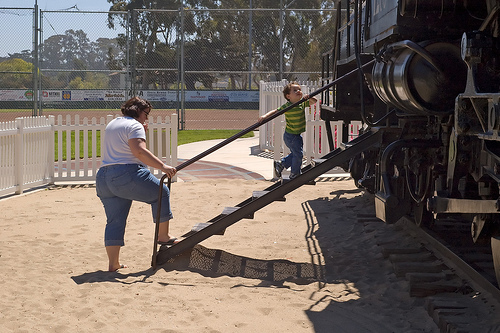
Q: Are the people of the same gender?
A: No, they are both male and female.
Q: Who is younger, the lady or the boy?
A: The boy is younger than the lady.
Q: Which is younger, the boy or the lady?
A: The boy is younger than the lady.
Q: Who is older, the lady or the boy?
A: The lady is older than the boy.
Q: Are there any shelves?
A: No, there are no shelves.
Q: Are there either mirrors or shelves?
A: No, there are no shelves or mirrors.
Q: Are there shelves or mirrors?
A: No, there are no shelves or mirrors.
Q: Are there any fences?
A: Yes, there is a fence.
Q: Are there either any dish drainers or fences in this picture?
A: Yes, there is a fence.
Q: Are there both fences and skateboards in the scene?
A: No, there is a fence but no skateboards.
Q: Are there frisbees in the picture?
A: No, there are no frisbees.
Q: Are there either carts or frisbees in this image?
A: No, there are no frisbees or carts.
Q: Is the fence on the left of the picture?
A: Yes, the fence is on the left of the image.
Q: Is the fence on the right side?
A: No, the fence is on the left of the image.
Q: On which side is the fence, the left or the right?
A: The fence is on the left of the image.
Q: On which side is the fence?
A: The fence is on the left of the image.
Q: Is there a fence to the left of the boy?
A: Yes, there is a fence to the left of the boy.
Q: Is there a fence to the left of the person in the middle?
A: Yes, there is a fence to the left of the boy.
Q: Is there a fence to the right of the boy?
A: No, the fence is to the left of the boy.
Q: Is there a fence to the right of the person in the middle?
A: No, the fence is to the left of the boy.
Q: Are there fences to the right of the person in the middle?
A: No, the fence is to the left of the boy.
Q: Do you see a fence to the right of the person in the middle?
A: No, the fence is to the left of the boy.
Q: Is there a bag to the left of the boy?
A: No, there is a fence to the left of the boy.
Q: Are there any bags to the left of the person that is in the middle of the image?
A: No, there is a fence to the left of the boy.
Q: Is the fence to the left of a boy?
A: Yes, the fence is to the left of a boy.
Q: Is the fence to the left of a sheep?
A: No, the fence is to the left of a boy.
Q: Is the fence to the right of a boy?
A: No, the fence is to the left of a boy.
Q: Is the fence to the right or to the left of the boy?
A: The fence is to the left of the boy.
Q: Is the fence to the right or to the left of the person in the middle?
A: The fence is to the left of the boy.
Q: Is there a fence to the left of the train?
A: Yes, there is a fence to the left of the train.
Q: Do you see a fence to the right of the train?
A: No, the fence is to the left of the train.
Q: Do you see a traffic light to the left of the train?
A: No, there is a fence to the left of the train.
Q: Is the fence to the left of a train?
A: Yes, the fence is to the left of a train.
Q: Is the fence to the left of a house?
A: No, the fence is to the left of a train.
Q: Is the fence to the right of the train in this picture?
A: No, the fence is to the left of the train.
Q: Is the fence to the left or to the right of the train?
A: The fence is to the left of the train.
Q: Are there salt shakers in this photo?
A: No, there are no salt shakers.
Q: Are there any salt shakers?
A: No, there are no salt shakers.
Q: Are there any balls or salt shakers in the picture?
A: No, there are no salt shakers or balls.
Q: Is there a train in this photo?
A: Yes, there is a train.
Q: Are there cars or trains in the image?
A: Yes, there is a train.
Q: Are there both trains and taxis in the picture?
A: No, there is a train but no taxis.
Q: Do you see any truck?
A: No, there are no trucks.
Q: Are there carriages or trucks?
A: No, there are no trucks or carriages.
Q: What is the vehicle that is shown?
A: The vehicle is a train.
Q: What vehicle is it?
A: The vehicle is a train.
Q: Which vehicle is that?
A: That is a train.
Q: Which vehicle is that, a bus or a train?
A: That is a train.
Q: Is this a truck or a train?
A: This is a train.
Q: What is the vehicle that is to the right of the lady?
A: The vehicle is a train.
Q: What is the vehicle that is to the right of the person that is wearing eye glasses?
A: The vehicle is a train.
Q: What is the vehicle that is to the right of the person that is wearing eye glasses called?
A: The vehicle is a train.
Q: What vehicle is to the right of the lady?
A: The vehicle is a train.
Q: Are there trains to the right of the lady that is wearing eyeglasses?
A: Yes, there is a train to the right of the lady.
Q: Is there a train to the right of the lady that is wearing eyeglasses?
A: Yes, there is a train to the right of the lady.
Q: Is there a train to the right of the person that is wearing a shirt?
A: Yes, there is a train to the right of the lady.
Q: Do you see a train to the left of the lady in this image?
A: No, the train is to the right of the lady.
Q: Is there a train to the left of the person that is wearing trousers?
A: No, the train is to the right of the lady.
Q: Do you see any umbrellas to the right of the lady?
A: No, there is a train to the right of the lady.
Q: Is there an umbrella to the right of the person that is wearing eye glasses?
A: No, there is a train to the right of the lady.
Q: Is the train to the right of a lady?
A: Yes, the train is to the right of a lady.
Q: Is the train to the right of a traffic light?
A: No, the train is to the right of a lady.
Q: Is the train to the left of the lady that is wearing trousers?
A: No, the train is to the right of the lady.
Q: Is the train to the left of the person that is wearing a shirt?
A: No, the train is to the right of the lady.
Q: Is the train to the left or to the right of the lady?
A: The train is to the right of the lady.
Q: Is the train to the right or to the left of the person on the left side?
A: The train is to the right of the lady.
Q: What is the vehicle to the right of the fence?
A: The vehicle is a train.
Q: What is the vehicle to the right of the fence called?
A: The vehicle is a train.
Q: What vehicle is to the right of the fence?
A: The vehicle is a train.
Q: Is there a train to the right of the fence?
A: Yes, there is a train to the right of the fence.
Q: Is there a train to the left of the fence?
A: No, the train is to the right of the fence.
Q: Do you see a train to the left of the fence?
A: No, the train is to the right of the fence.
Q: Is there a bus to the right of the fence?
A: No, there is a train to the right of the fence.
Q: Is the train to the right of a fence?
A: Yes, the train is to the right of a fence.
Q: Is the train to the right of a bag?
A: No, the train is to the right of a fence.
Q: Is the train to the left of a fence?
A: No, the train is to the right of a fence.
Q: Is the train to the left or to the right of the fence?
A: The train is to the right of the fence.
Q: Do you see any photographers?
A: No, there are no photographers.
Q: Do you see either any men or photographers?
A: No, there are no photographers or men.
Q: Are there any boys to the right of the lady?
A: Yes, there is a boy to the right of the lady.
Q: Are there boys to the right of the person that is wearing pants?
A: Yes, there is a boy to the right of the lady.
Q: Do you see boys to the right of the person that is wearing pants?
A: Yes, there is a boy to the right of the lady.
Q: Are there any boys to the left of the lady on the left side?
A: No, the boy is to the right of the lady.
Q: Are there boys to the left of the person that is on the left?
A: No, the boy is to the right of the lady.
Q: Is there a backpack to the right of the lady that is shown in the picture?
A: No, there is a boy to the right of the lady.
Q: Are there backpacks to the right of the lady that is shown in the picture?
A: No, there is a boy to the right of the lady.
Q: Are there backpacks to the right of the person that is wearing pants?
A: No, there is a boy to the right of the lady.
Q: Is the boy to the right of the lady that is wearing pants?
A: Yes, the boy is to the right of the lady.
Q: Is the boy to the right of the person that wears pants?
A: Yes, the boy is to the right of the lady.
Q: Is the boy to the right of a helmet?
A: No, the boy is to the right of the lady.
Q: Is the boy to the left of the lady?
A: No, the boy is to the right of the lady.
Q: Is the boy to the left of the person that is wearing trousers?
A: No, the boy is to the right of the lady.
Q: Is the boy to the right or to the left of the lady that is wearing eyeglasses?
A: The boy is to the right of the lady.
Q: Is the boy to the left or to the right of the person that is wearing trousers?
A: The boy is to the right of the lady.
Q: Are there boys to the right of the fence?
A: Yes, there is a boy to the right of the fence.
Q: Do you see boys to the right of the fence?
A: Yes, there is a boy to the right of the fence.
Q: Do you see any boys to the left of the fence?
A: No, the boy is to the right of the fence.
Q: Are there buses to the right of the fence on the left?
A: No, there is a boy to the right of the fence.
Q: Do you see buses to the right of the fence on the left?
A: No, there is a boy to the right of the fence.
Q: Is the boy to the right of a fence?
A: Yes, the boy is to the right of a fence.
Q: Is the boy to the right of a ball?
A: No, the boy is to the right of a fence.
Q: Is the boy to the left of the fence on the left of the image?
A: No, the boy is to the right of the fence.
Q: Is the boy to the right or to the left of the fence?
A: The boy is to the right of the fence.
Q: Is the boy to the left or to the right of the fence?
A: The boy is to the right of the fence.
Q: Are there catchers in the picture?
A: No, there are no catchers.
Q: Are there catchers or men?
A: No, there are no catchers or men.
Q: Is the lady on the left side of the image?
A: Yes, the lady is on the left of the image.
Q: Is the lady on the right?
A: No, the lady is on the left of the image.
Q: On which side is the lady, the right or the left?
A: The lady is on the left of the image.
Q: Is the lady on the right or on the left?
A: The lady is on the left of the image.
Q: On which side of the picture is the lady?
A: The lady is on the left of the image.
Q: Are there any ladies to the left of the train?
A: Yes, there is a lady to the left of the train.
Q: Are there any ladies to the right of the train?
A: No, the lady is to the left of the train.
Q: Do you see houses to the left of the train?
A: No, there is a lady to the left of the train.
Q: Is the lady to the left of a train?
A: Yes, the lady is to the left of a train.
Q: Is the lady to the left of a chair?
A: No, the lady is to the left of a train.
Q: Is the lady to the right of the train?
A: No, the lady is to the left of the train.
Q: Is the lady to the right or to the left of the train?
A: The lady is to the left of the train.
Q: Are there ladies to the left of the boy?
A: Yes, there is a lady to the left of the boy.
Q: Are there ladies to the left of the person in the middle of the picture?
A: Yes, there is a lady to the left of the boy.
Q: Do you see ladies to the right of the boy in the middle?
A: No, the lady is to the left of the boy.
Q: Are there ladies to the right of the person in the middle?
A: No, the lady is to the left of the boy.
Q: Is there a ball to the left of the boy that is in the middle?
A: No, there is a lady to the left of the boy.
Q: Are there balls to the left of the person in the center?
A: No, there is a lady to the left of the boy.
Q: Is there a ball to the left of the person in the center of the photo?
A: No, there is a lady to the left of the boy.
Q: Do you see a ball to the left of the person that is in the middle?
A: No, there is a lady to the left of the boy.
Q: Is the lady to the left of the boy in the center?
A: Yes, the lady is to the left of the boy.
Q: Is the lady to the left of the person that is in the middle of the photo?
A: Yes, the lady is to the left of the boy.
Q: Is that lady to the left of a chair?
A: No, the lady is to the left of the boy.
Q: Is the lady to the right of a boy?
A: No, the lady is to the left of a boy.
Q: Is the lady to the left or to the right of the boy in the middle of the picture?
A: The lady is to the left of the boy.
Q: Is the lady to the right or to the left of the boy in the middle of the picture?
A: The lady is to the left of the boy.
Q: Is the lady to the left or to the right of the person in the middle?
A: The lady is to the left of the boy.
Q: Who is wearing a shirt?
A: The lady is wearing a shirt.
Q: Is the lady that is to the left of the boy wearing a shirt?
A: Yes, the lady is wearing a shirt.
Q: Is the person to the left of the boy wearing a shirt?
A: Yes, the lady is wearing a shirt.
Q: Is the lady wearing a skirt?
A: No, the lady is wearing a shirt.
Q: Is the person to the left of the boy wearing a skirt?
A: No, the lady is wearing a shirt.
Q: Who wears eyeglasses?
A: The lady wears eyeglasses.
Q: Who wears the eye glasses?
A: The lady wears eyeglasses.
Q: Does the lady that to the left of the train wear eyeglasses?
A: Yes, the lady wears eyeglasses.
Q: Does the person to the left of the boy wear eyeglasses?
A: Yes, the lady wears eyeglasses.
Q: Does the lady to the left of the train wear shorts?
A: No, the lady wears eyeglasses.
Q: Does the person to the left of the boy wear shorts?
A: No, the lady wears eyeglasses.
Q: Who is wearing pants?
A: The lady is wearing pants.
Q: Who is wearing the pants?
A: The lady is wearing pants.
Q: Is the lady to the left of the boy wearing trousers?
A: Yes, the lady is wearing trousers.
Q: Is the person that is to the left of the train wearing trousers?
A: Yes, the lady is wearing trousers.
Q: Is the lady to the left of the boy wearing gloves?
A: No, the lady is wearing trousers.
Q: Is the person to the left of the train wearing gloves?
A: No, the lady is wearing trousers.